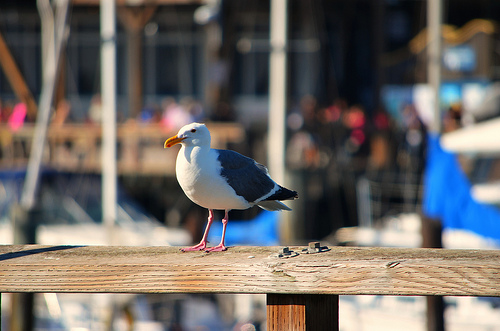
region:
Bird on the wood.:
[159, 118, 300, 260]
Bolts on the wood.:
[274, 236, 331, 262]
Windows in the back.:
[0, 33, 313, 103]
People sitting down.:
[155, 90, 205, 126]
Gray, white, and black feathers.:
[157, 120, 296, 221]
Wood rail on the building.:
[0, 118, 255, 173]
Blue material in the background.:
[410, 131, 498, 244]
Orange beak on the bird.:
[157, 115, 203, 151]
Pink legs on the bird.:
[180, 198, 235, 259]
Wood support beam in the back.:
[0, 33, 46, 124]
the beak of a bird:
[156, 116, 196, 166]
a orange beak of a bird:
[151, 122, 193, 163]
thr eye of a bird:
[183, 115, 206, 145]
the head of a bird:
[155, 113, 230, 188]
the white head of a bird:
[153, 118, 226, 175]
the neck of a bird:
[176, 128, 225, 162]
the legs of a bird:
[166, 200, 263, 285]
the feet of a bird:
[177, 229, 249, 277]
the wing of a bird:
[163, 142, 328, 220]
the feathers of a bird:
[161, 140, 325, 216]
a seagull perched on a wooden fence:
[159, 115, 303, 265]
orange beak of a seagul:
[162, 130, 192, 150]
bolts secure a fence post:
[259, 238, 346, 329]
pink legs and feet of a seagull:
[176, 200, 232, 256]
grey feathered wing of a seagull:
[216, 146, 281, 207]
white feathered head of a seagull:
[161, 120, 211, 150]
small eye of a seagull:
[187, 126, 197, 135]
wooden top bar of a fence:
[0, 240, 498, 300]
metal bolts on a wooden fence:
[269, 240, 331, 258]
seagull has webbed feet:
[161, 119, 299, 254]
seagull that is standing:
[117, 107, 303, 257]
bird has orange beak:
[149, 120, 186, 161]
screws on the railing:
[274, 216, 346, 289]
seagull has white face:
[158, 115, 240, 220]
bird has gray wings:
[216, 139, 299, 227]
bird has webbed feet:
[182, 197, 257, 303]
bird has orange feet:
[179, 203, 242, 270]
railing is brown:
[44, 228, 234, 308]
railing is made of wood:
[330, 242, 467, 308]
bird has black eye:
[186, 121, 216, 148]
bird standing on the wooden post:
[151, 110, 288, 260]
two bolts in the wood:
[267, 238, 329, 258]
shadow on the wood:
[1, 236, 87, 265]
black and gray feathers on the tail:
[258, 182, 308, 216]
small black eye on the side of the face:
[189, 126, 201, 133]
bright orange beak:
[161, 131, 181, 149]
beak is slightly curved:
[161, 130, 183, 153]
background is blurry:
[3, 0, 499, 322]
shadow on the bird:
[180, 139, 198, 174]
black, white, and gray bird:
[157, 110, 305, 254]